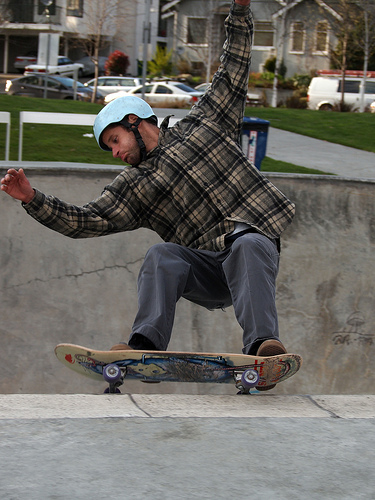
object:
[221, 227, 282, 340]
leg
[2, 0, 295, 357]
man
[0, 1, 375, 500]
park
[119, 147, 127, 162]
mouth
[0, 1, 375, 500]
outside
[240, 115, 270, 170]
trash can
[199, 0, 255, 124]
arm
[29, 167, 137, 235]
arm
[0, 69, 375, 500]
ground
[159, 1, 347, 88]
blue house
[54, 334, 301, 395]
skateboard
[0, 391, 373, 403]
edge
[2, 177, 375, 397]
ramp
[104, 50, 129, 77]
red bush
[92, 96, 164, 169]
helmet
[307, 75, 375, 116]
van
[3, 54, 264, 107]
vehicles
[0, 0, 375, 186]
street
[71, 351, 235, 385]
bottom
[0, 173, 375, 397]
halfpipe